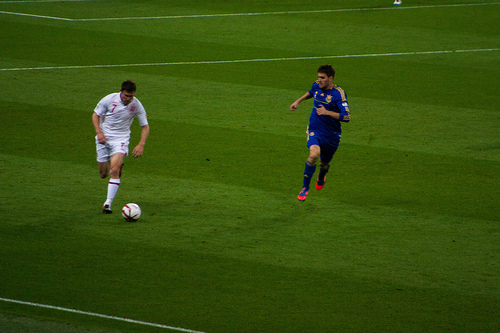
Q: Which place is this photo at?
A: It is at the field.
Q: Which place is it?
A: It is a field.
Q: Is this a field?
A: Yes, it is a field.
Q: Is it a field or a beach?
A: It is a field.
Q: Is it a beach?
A: No, it is a field.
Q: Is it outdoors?
A: Yes, it is outdoors.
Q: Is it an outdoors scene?
A: Yes, it is outdoors.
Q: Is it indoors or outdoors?
A: It is outdoors.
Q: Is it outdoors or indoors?
A: It is outdoors.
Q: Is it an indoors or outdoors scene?
A: It is outdoors.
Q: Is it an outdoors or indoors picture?
A: It is outdoors.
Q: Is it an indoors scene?
A: No, it is outdoors.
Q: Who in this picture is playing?
A: The man is playing.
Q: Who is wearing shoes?
A: The man is wearing shoes.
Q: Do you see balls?
A: Yes, there is a ball.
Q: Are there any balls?
A: Yes, there is a ball.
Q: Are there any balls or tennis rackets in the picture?
A: Yes, there is a ball.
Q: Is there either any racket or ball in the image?
A: Yes, there is a ball.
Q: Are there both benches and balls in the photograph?
A: No, there is a ball but no benches.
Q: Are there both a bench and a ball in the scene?
A: No, there is a ball but no benches.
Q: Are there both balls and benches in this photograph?
A: No, there is a ball but no benches.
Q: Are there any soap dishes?
A: No, there are no soap dishes.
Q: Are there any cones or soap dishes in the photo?
A: No, there are no soap dishes or cones.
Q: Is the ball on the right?
A: No, the ball is on the left of the image.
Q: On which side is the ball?
A: The ball is on the left of the image.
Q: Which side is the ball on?
A: The ball is on the left of the image.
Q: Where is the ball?
A: The ball is on the field.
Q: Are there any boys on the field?
A: No, there is a ball on the field.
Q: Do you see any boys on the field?
A: No, there is a ball on the field.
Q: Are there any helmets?
A: No, there are no helmets.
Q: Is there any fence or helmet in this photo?
A: No, there are no helmets or fences.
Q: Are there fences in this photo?
A: No, there are no fences.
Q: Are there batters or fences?
A: No, there are no fences or batters.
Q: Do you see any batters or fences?
A: No, there are no fences or batters.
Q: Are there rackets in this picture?
A: No, there are no rackets.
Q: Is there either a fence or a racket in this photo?
A: No, there are no rackets or fences.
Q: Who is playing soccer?
A: The man is playing soccer.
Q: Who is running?
A: The man is running.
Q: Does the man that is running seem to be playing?
A: Yes, the man is playing.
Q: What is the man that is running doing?
A: The man is playing.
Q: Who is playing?
A: The man is playing.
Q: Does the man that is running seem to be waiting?
A: No, the man is playing.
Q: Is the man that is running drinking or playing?
A: The man is playing.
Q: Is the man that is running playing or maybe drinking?
A: The man is playing.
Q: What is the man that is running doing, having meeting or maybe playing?
A: The man is playing.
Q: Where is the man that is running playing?
A: The man is playing on the field.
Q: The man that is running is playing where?
A: The man is playing on the field.